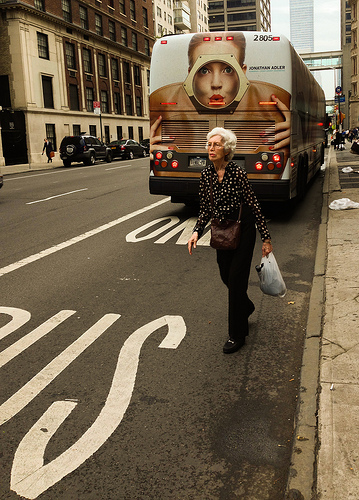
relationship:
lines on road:
[0, 188, 173, 293] [0, 91, 318, 494]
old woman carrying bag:
[185, 119, 289, 358] [254, 249, 287, 300]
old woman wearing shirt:
[185, 119, 289, 358] [168, 161, 284, 253]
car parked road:
[57, 133, 113, 164] [0, 160, 318, 495]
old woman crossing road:
[185, 118, 281, 331] [0, 160, 318, 495]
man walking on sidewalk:
[41, 137, 54, 162] [0, 157, 62, 177]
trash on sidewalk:
[325, 194, 357, 207] [283, 136, 355, 498]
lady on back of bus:
[149, 31, 291, 159] [148, 31, 324, 215]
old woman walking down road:
[185, 119, 289, 358] [0, 160, 318, 495]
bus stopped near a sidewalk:
[148, 31, 324, 215] [320, 127, 357, 496]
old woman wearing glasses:
[185, 119, 289, 358] [205, 140, 226, 148]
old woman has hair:
[185, 119, 289, 358] [205, 125, 237, 162]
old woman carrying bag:
[185, 119, 289, 358] [207, 214, 242, 251]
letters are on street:
[0, 302, 188, 500] [15, 238, 304, 349]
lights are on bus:
[118, 122, 305, 191] [148, 31, 324, 215]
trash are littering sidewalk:
[325, 194, 359, 214] [333, 209, 357, 279]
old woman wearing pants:
[185, 119, 289, 358] [212, 224, 257, 339]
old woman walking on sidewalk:
[185, 119, 289, 358] [303, 142, 357, 498]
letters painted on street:
[14, 292, 131, 355] [31, 174, 143, 289]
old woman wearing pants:
[185, 119, 289, 358] [216, 215, 256, 335]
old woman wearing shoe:
[185, 119, 289, 358] [221, 331, 246, 352]